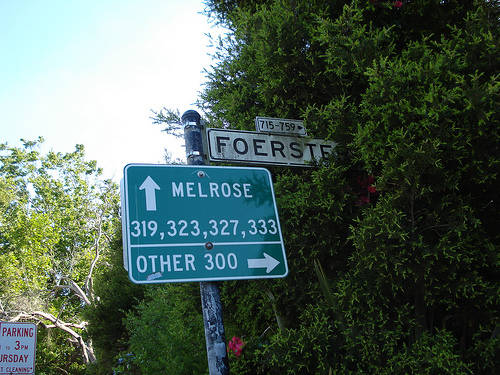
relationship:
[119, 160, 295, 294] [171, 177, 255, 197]
sign has letters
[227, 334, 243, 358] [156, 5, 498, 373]
pink object visible in tree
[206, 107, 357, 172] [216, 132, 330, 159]
sign with letters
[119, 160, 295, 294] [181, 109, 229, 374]
sign on pole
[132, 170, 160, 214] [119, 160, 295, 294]
arrow on sign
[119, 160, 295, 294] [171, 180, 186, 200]
sign with letters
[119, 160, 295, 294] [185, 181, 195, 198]
sign with letters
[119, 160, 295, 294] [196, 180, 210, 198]
sign with letters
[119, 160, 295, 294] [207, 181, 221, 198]
sign with letters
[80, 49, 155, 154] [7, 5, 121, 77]
clouds in sky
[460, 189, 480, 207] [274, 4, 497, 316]
part of a bush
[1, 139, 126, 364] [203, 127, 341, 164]
tree standing beside sign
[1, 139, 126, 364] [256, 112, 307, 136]
tree standing beside sign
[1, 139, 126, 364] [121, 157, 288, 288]
tree standing beside sign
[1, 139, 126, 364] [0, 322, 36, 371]
tree standing beside parking sign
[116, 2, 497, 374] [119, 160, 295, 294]
trees standing beside sign